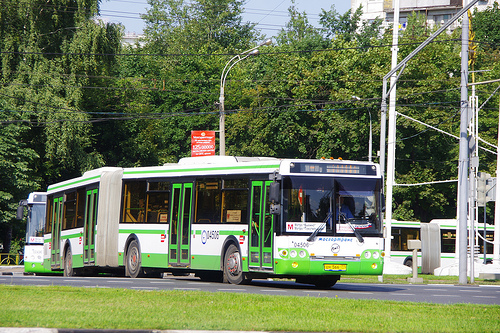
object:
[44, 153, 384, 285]
bus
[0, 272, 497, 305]
street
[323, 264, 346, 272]
license plate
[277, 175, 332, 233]
windshield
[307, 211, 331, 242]
wiper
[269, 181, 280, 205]
mirror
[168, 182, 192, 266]
door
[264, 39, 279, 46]
light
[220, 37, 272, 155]
pole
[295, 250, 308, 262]
headlight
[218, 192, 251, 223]
window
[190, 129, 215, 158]
sign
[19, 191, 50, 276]
bus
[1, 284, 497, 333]
grass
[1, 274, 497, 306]
road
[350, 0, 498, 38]
building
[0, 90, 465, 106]
power line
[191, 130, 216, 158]
banner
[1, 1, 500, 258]
trees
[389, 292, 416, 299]
white mark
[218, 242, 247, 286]
wheel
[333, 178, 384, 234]
windshield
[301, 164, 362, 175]
marquee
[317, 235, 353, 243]
writing